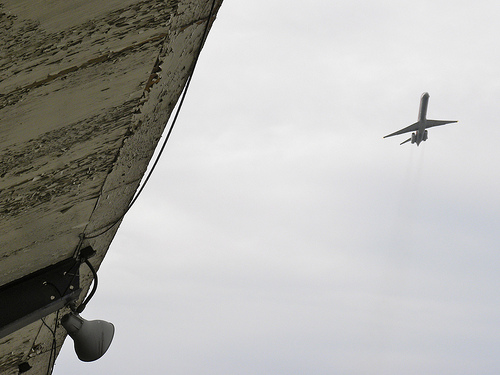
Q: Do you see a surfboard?
A: No, there are no surfboards.